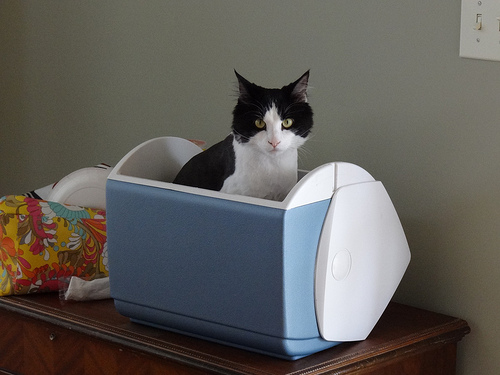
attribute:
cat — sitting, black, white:
[173, 68, 314, 201]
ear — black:
[285, 69, 311, 105]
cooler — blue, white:
[106, 136, 412, 361]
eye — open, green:
[281, 118, 293, 128]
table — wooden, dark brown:
[0, 292, 470, 373]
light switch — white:
[474, 14, 483, 31]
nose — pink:
[269, 137, 282, 148]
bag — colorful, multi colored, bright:
[0, 195, 108, 295]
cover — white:
[314, 180, 412, 342]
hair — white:
[219, 98, 313, 202]